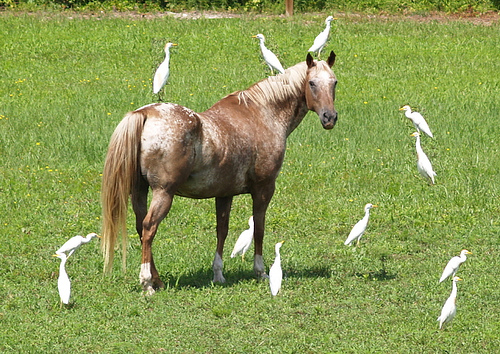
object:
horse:
[99, 51, 338, 293]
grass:
[2, 0, 38, 59]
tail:
[98, 111, 141, 275]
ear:
[305, 52, 316, 69]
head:
[305, 54, 339, 130]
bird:
[308, 15, 339, 64]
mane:
[247, 60, 317, 108]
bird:
[268, 240, 285, 298]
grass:
[157, 261, 394, 295]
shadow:
[145, 264, 329, 292]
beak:
[250, 35, 258, 38]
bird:
[251, 30, 287, 74]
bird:
[150, 40, 179, 104]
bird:
[52, 253, 76, 310]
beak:
[51, 254, 59, 258]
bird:
[409, 131, 438, 186]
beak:
[408, 133, 415, 137]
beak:
[171, 41, 179, 48]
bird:
[342, 202, 379, 248]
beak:
[372, 203, 379, 212]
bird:
[439, 249, 474, 283]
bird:
[436, 276, 464, 330]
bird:
[56, 231, 101, 255]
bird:
[398, 103, 435, 138]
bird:
[231, 216, 258, 261]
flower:
[106, 111, 113, 116]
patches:
[162, 124, 174, 135]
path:
[1, 4, 275, 19]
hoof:
[251, 268, 269, 279]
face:
[309, 65, 337, 117]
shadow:
[361, 252, 397, 282]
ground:
[345, 250, 417, 300]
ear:
[327, 49, 337, 67]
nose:
[323, 110, 340, 122]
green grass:
[354, 107, 383, 143]